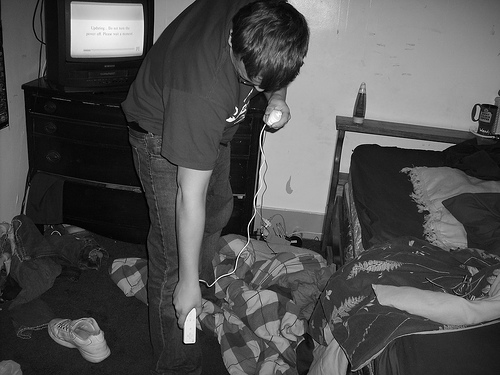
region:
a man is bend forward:
[108, 0, 321, 374]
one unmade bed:
[315, 114, 499, 367]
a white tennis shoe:
[39, 308, 116, 370]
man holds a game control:
[113, 0, 332, 363]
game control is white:
[161, 100, 293, 355]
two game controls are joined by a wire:
[176, 105, 293, 357]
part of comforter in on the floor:
[112, 219, 497, 374]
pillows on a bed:
[388, 135, 499, 254]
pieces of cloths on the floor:
[1, 201, 116, 368]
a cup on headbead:
[465, 97, 499, 146]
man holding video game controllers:
[128, 0, 318, 373]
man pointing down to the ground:
[122, 0, 314, 373]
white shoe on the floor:
[47, 312, 113, 360]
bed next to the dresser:
[321, 115, 498, 374]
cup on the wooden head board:
[471, 99, 496, 144]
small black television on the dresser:
[40, 0, 159, 100]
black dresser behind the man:
[23, 72, 275, 244]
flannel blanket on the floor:
[110, 238, 332, 368]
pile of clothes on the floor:
[0, 208, 104, 340]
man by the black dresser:
[122, 0, 307, 370]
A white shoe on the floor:
[46, 314, 113, 359]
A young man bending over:
[130, 2, 312, 373]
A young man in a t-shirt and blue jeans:
[122, 0, 310, 373]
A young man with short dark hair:
[124, 5, 313, 374]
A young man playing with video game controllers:
[125, 2, 310, 374]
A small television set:
[49, 0, 156, 90]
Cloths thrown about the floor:
[115, 234, 339, 369]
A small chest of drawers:
[24, 67, 255, 244]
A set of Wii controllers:
[183, 105, 283, 341]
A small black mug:
[468, 101, 498, 142]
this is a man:
[131, 4, 323, 355]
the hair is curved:
[236, 8, 303, 65]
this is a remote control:
[183, 305, 198, 344]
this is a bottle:
[351, 82, 370, 122]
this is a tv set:
[53, 0, 144, 82]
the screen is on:
[77, 5, 139, 52]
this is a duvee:
[253, 247, 315, 374]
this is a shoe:
[46, 312, 109, 359]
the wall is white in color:
[386, 2, 474, 101]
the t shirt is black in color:
[163, 24, 220, 148]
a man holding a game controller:
[123, 0, 306, 350]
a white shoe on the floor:
[31, 300, 116, 360]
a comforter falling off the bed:
[230, 219, 477, 361]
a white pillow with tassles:
[406, 159, 498, 244]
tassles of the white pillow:
[403, 160, 442, 246]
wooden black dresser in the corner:
[51, 103, 144, 234]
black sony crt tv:
[34, 0, 147, 95]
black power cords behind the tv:
[21, 7, 57, 106]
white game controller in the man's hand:
[168, 287, 213, 357]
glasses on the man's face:
[232, 67, 291, 99]